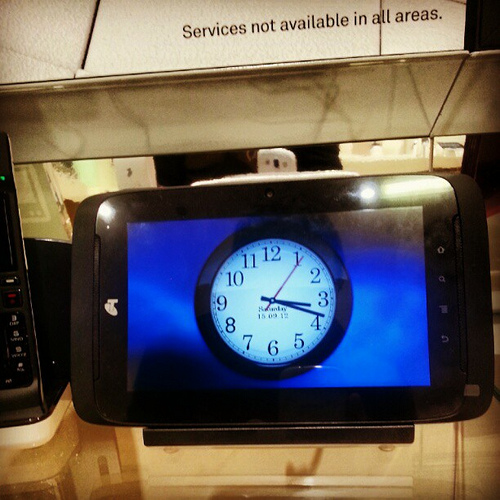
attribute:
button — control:
[439, 331, 449, 343]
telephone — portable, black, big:
[70, 168, 491, 433]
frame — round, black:
[187, 221, 349, 400]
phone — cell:
[77, 173, 489, 440]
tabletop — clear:
[1, 155, 481, 489]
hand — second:
[260, 295, 324, 318]